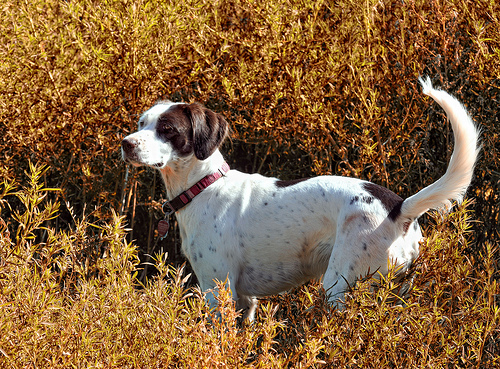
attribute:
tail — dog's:
[374, 63, 477, 241]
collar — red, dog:
[155, 162, 240, 219]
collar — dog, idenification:
[141, 164, 255, 224]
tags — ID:
[152, 195, 180, 227]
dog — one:
[128, 83, 458, 320]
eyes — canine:
[120, 110, 200, 144]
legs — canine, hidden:
[189, 251, 399, 316]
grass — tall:
[112, 268, 498, 366]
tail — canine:
[393, 75, 485, 249]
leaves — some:
[101, 285, 188, 338]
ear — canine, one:
[190, 100, 231, 164]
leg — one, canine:
[316, 230, 381, 315]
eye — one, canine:
[163, 120, 182, 147]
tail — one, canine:
[395, 75, 498, 257]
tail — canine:
[393, 60, 476, 230]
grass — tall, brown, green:
[2, 4, 499, 367]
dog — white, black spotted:
[121, 75, 484, 322]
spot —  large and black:
[165, 102, 224, 150]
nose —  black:
[107, 126, 148, 195]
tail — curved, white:
[396, 70, 484, 224]